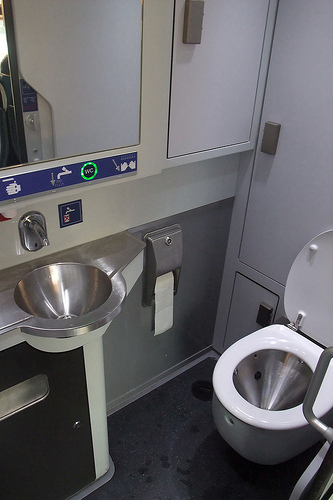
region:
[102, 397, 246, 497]
water stains on the floor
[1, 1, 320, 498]
a scene of a toilet stall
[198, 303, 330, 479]
a silver and white toilet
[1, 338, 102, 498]
a black and silver trashcan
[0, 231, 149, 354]
a silver sink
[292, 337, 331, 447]
a hand rail on the right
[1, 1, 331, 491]
a scene inside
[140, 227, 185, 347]
a roll of toilet paper in a dispenser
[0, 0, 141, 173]
a mirror to see in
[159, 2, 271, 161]
a cabinet door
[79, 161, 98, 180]
a black button with green light around it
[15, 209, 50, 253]
a silver water faucet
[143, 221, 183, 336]
a silver toiler paper dispenser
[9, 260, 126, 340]
a silver sink bowl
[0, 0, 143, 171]
a mirror reflecting a white wall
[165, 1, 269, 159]
a white door with a silver box on it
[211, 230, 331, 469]
a white toilet with an open lid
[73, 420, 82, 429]
a silver lock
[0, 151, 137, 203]
a blue panel with various signs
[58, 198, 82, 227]
blue and white sign on a wall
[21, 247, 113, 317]
this is a sink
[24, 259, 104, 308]
the sink is metallic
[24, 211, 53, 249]
this is a tap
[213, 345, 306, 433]
this is a toilet sink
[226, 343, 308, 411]
the top is open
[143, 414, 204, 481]
this is the floor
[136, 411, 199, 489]
the floor is black in color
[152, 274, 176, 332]
this is a tissue paper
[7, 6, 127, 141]
this is a mirror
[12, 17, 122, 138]
the mirror is clear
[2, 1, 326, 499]
the scene is in a bathroom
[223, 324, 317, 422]
the toiletseat is open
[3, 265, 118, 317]
the sink is siler in colour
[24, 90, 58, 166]
a door handle is reflected on the mirror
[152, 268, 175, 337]
the tissue paper is hanging o ut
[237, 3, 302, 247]
the cupboard is locked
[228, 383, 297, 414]
toiletseat is white in colour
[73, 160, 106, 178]
the sign is shiny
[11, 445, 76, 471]
the door is black in colour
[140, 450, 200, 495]
water is spilt on the floor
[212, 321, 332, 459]
STAINLESS STEEL TOILET BOWL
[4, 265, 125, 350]
STAINLESS STEEL HAND SINK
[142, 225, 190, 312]
STAINLESS STEEL TOILET PAPER HOLDER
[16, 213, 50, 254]
CHROME WATER FAUCET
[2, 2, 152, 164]
MIRROR IN A BATHROOM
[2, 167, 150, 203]
SINAGE ABOVE THE SINK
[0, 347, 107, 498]
CABINET UNDER SINK WITH LOCK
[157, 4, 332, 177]
STORAGE AREAS WITH WHITE DOORS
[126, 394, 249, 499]
BLACK FLOORING IN BATHROOM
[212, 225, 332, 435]
WHITE TOILET SEAT ON STEEL TOILET